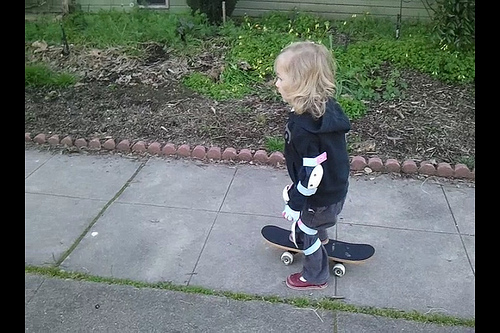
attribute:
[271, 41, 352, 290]
girl — skating, little, small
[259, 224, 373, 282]
skateboard — black, small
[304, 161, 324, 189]
elbow pad — white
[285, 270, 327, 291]
shoe — red, brown, baby jane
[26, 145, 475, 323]
sidewalk — concrete, partial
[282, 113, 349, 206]
jacket — black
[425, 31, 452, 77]
flower — yellow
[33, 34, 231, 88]
clump of leaves — dead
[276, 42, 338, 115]
hair — blond, wavy, long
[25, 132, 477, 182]
brick trim — red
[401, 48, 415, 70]
flower — yellow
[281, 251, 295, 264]
front wheel — white